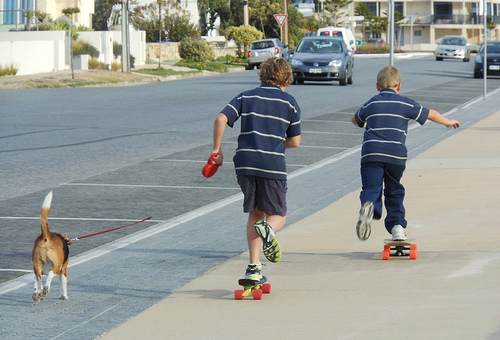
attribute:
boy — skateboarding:
[351, 65, 460, 241]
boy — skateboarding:
[211, 57, 301, 282]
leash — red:
[68, 176, 207, 243]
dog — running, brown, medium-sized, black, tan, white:
[31, 189, 70, 298]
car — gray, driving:
[287, 35, 356, 85]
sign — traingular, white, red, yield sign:
[273, 14, 289, 25]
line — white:
[61, 182, 241, 189]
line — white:
[3, 215, 162, 224]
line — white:
[300, 143, 345, 151]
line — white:
[299, 128, 363, 135]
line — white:
[306, 118, 353, 125]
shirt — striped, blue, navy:
[355, 90, 428, 163]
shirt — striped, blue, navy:
[220, 84, 301, 181]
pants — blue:
[361, 160, 407, 234]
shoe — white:
[390, 225, 407, 240]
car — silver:
[434, 34, 471, 62]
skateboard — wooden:
[382, 238, 417, 260]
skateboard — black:
[235, 278, 271, 299]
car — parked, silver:
[247, 38, 289, 69]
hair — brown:
[259, 57, 294, 87]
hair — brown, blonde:
[375, 67, 401, 91]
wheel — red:
[252, 289, 262, 300]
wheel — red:
[260, 283, 271, 293]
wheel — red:
[233, 289, 244, 299]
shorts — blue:
[235, 172, 288, 217]